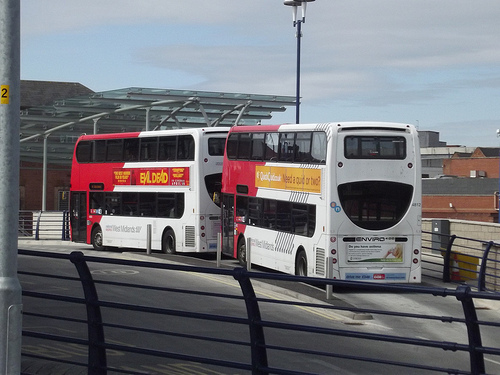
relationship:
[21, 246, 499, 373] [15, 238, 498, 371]
rail on street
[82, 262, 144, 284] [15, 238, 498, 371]
white circle on street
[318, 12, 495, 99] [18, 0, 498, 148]
clouds on blue sky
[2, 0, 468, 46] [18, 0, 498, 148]
cloud in blue sky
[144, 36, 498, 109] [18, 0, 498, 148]
cloud in blue sky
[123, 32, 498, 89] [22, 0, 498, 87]
clouds in sky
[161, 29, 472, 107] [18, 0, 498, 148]
white clouds in blue sky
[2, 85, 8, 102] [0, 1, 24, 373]
number 2 on pole